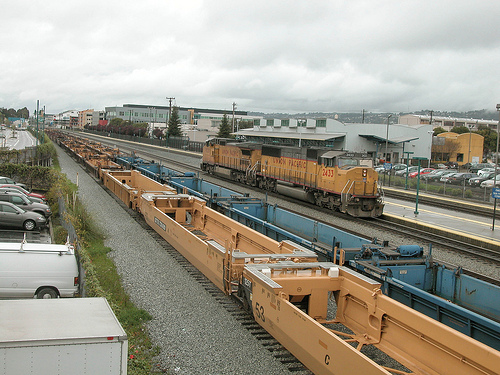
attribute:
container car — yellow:
[137, 195, 320, 298]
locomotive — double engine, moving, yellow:
[200, 134, 401, 224]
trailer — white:
[4, 297, 137, 374]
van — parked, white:
[3, 232, 86, 299]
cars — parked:
[1, 172, 55, 239]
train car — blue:
[349, 257, 500, 344]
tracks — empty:
[391, 212, 499, 267]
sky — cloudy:
[10, 3, 498, 127]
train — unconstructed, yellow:
[240, 272, 492, 374]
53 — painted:
[249, 299, 273, 329]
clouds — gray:
[218, 19, 342, 76]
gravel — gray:
[106, 224, 145, 261]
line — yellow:
[456, 214, 474, 221]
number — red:
[321, 168, 336, 178]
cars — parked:
[392, 160, 500, 192]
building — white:
[254, 113, 444, 161]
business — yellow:
[434, 133, 489, 166]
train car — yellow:
[75, 145, 179, 194]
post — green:
[414, 155, 428, 216]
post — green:
[397, 149, 415, 194]